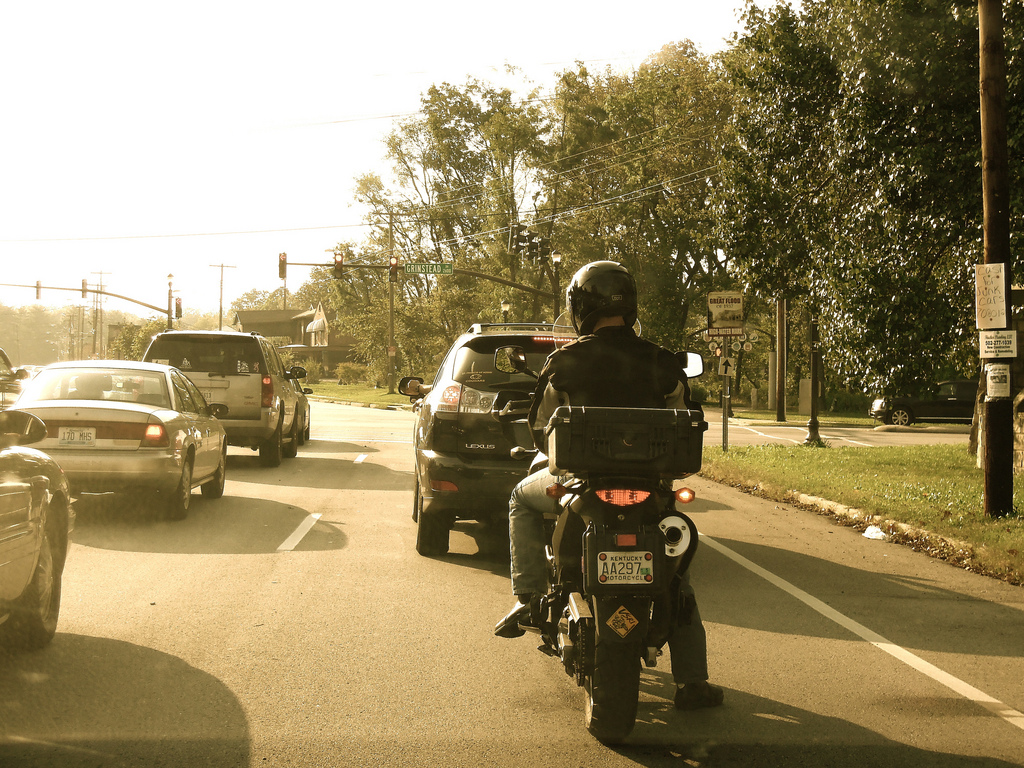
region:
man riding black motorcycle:
[500, 244, 742, 739]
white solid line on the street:
[685, 518, 1019, 763]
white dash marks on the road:
[253, 428, 390, 561]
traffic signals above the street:
[10, 210, 555, 334]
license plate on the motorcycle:
[598, 548, 653, 593]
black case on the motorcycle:
[541, 398, 698, 481]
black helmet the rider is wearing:
[562, 257, 636, 324]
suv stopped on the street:
[141, 307, 310, 460]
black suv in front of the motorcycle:
[405, 317, 687, 561]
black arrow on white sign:
[715, 354, 739, 371]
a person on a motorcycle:
[526, 259, 719, 743]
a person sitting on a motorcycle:
[510, 254, 717, 727]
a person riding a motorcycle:
[498, 283, 745, 751]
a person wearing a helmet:
[560, 263, 659, 331]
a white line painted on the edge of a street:
[728, 539, 1019, 742]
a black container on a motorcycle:
[537, 396, 711, 486]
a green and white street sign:
[398, 253, 462, 283]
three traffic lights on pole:
[257, 240, 526, 295]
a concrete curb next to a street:
[754, 480, 988, 597]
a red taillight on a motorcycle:
[575, 484, 667, 514]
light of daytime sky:
[0, 0, 807, 315]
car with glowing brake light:
[17, 361, 224, 518]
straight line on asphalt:
[697, 529, 1018, 723]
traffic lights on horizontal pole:
[273, 248, 540, 294]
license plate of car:
[52, 425, 97, 444]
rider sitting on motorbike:
[495, 254, 715, 741]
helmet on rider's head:
[564, 257, 634, 331]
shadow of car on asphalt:
[67, 490, 344, 551]